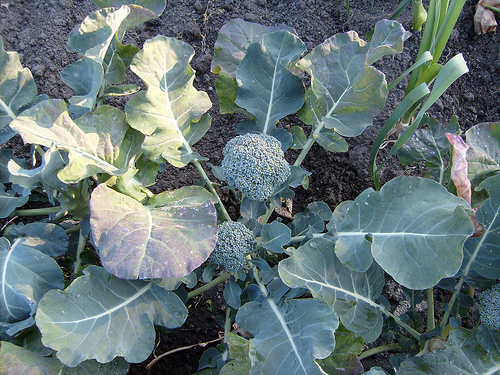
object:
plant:
[4, 1, 498, 373]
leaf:
[472, 4, 496, 36]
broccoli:
[220, 130, 291, 201]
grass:
[365, 2, 466, 186]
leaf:
[299, 20, 410, 136]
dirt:
[2, 0, 499, 373]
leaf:
[90, 184, 217, 279]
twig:
[147, 335, 222, 366]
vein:
[294, 85, 348, 166]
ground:
[2, 2, 496, 374]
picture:
[2, 2, 499, 373]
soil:
[3, 0, 497, 371]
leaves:
[122, 34, 216, 166]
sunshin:
[2, 2, 220, 288]